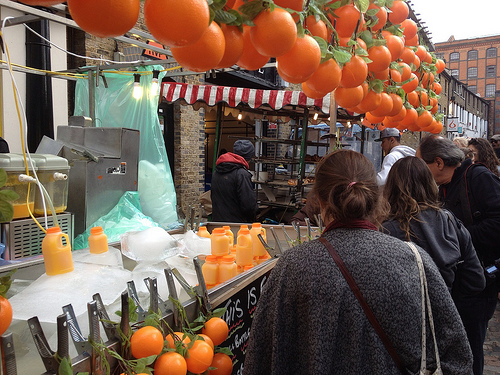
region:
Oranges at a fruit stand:
[65, 1, 448, 136]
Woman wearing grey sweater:
[240, 141, 476, 373]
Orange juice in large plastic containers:
[2, 147, 73, 219]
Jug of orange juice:
[36, 223, 76, 273]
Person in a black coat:
[210, 137, 262, 222]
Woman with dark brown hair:
[384, 156, 484, 296]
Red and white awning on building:
[159, 79, 329, 120]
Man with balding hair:
[414, 130, 499, 297]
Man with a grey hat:
[372, 127, 414, 185]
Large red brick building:
[435, 30, 498, 110]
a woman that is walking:
[248, 142, 452, 363]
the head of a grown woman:
[295, 142, 380, 233]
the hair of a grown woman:
[324, 181, 372, 216]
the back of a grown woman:
[250, 238, 474, 369]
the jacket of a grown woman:
[301, 265, 426, 363]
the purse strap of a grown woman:
[324, 271, 366, 298]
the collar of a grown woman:
[324, 222, 382, 249]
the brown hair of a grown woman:
[390, 191, 431, 229]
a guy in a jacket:
[192, 125, 277, 215]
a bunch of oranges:
[120, 288, 237, 365]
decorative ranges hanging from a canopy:
[21, 0, 448, 135]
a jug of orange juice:
[41, 225, 73, 274]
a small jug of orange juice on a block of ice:
[88, 225, 108, 255]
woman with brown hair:
[313, 150, 381, 222]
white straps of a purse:
[406, 237, 440, 373]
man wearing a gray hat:
[231, 137, 253, 162]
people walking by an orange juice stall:
[241, 133, 498, 373]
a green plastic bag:
[74, 63, 175, 247]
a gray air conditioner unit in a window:
[5, 210, 74, 261]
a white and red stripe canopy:
[155, 82, 331, 115]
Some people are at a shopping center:
[25, 10, 496, 343]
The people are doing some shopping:
[22, 13, 480, 359]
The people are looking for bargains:
[21, 12, 496, 349]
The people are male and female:
[25, 5, 497, 350]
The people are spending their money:
[0, 10, 496, 365]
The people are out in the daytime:
[13, 5, 494, 365]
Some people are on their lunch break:
[20, 23, 497, 354]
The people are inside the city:
[22, 3, 492, 365]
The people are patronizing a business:
[28, 5, 491, 365]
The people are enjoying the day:
[33, 44, 495, 344]